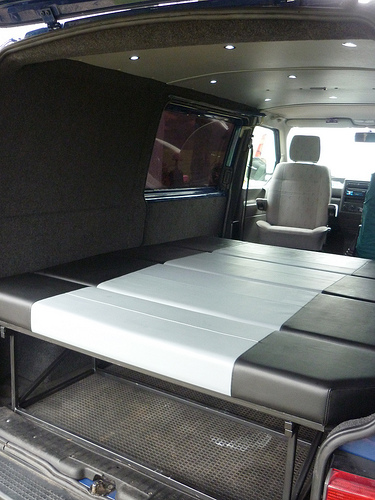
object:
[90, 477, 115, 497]
latch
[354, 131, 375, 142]
mirror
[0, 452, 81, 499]
bumper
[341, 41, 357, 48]
light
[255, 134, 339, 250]
seat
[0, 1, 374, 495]
black interior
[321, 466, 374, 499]
light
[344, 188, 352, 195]
light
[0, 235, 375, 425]
cushions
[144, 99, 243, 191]
mirror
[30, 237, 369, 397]
white strip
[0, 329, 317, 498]
storage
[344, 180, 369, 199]
radio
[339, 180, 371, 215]
dash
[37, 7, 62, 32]
latch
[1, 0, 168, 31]
trunk door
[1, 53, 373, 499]
vehicle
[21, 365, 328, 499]
bumps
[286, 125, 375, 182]
window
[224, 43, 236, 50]
light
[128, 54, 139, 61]
light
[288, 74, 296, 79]
light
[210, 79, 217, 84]
light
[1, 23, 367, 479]
interior